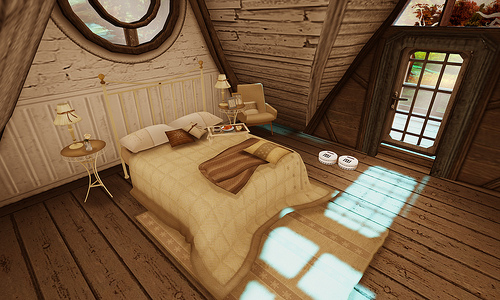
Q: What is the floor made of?
A: Brown wood.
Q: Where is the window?
A: On top of the bed.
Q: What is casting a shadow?
A: A door with glass panes.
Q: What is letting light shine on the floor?
A: A brown wooden door with windows on it.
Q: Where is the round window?
A: In a room.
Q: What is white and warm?
A: A blanket on a bed.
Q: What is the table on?
A: A wooden floor in a room.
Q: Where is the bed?
A: In the room.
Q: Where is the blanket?
A: On the bed.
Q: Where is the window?
A: In the room.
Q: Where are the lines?
A: On the ground.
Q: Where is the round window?
A: Above the bed.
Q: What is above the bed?
A: A round window.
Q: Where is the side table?
A: By the bed.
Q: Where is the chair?
A: Right of bed.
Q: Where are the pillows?
A: On the bed.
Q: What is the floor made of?
A: Wood.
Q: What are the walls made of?
A: Wood.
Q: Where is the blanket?
A: On the bed.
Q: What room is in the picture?
A: Bedroom.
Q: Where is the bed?
A: Between two lamp tables.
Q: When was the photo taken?
A: Daytime.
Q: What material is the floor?
A: Wood.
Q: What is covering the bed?
A: Comforter.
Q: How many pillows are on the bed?
A: Three.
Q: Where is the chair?
A: Right side of the bed.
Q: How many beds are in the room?
A: One.